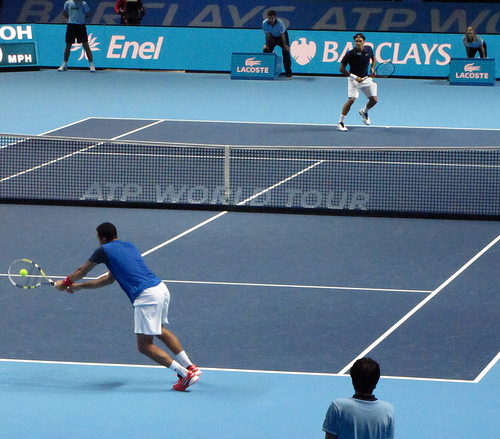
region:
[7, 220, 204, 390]
Man hitting the tennis ball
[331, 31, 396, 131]
Man waiting for the tennis ball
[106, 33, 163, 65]
Enel is an advertiser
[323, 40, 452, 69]
Barclays is an advertiser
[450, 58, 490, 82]
Lacoste is an advertiser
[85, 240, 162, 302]
Man wearing a blue shirt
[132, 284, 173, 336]
Man wearing white shorts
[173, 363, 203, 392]
Man wearing red footwear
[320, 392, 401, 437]
Man wearing light blue shirt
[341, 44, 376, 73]
Man wearing black shirt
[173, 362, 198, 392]
tennis player's red shoes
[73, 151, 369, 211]
tennis net that says ATP World Tour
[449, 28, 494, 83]
woman standing behind a Lacoste sign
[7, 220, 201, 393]
tennis player wearing red shoes and a blue shirt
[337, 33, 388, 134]
tennis player wearing white shorts and a black shirt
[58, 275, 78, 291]
tennis player's red wristband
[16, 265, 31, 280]
green tennis ball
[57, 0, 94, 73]
standing person wearing black shorts and a blue shirt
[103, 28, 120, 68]
White letter on blue wall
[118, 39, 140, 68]
White letter on blue wall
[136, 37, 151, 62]
White letter on blue wall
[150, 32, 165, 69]
White letter on blue wall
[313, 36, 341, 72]
White letter on blue wall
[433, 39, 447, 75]
White letter on blue wall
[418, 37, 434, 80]
White letter on blue wall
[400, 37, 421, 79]
White letter on blue wall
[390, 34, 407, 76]
White letter on blue wall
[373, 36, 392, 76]
White letter on blue wall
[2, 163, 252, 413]
the man is playing tennis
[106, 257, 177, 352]
the man is wearing shorts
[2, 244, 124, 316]
man is holding a racket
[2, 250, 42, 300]
the ball is lime green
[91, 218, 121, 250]
the man has dark hair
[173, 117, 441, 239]
the net is black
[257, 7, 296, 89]
Man in blue shirt observing.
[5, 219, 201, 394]
Man in dark blue shirt hitting tennis ball.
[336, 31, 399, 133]
Man holding a tennis racket.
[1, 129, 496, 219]
Tennis court net with white trim.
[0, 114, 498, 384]
Dark blue and white tennis court.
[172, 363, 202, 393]
Red and white pair of sneakers.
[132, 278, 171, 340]
White loose fitting pair of shorts.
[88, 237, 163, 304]
fitted navy blue and black shirt.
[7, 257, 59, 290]
Tennis racket with black stripes.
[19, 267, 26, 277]
Green tennis ball.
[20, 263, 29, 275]
a green tennis ball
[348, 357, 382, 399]
a man's short cut black hair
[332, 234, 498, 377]
a long white line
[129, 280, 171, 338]
a man's white shorts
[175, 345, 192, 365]
a man's white socks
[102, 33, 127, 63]
a capital white letter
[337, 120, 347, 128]
a man's tennis shoe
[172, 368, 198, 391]
a red and white tennis shoe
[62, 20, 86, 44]
a man's black shorts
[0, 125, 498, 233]
a long black and white tennis net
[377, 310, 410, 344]
Line on a court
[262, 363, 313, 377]
Line on a court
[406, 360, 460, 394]
Line on a court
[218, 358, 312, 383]
Line on a court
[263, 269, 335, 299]
Line on a court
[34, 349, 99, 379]
Line on a court